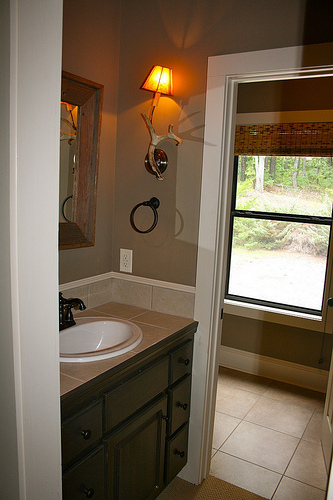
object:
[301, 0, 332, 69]
part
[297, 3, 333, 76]
ventilation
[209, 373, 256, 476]
part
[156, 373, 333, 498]
floor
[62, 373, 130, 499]
part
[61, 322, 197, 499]
cupboard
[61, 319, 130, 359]
part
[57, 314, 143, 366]
sink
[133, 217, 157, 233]
part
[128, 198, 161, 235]
handle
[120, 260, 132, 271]
part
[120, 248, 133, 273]
switch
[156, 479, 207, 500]
part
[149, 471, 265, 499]
carpet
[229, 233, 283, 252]
part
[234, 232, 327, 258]
boundary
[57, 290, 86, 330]
faucet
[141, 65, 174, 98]
shade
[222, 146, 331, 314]
window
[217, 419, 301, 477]
tile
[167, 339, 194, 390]
drawer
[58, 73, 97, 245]
mirror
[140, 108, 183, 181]
antler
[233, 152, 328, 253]
forest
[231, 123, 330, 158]
blinds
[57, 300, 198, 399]
counter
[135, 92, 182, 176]
fixture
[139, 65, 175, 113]
light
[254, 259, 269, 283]
grass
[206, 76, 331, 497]
door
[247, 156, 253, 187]
leaves